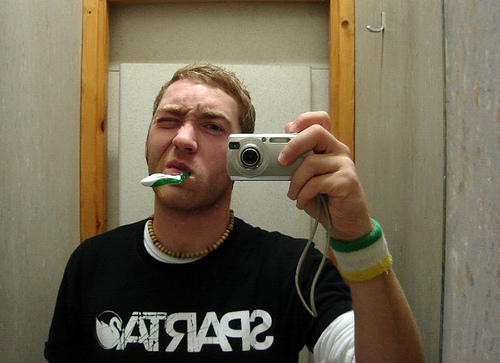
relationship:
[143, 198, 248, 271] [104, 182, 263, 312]
necklace around neck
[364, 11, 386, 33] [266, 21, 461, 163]
handle on wall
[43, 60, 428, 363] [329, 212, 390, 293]
man has wrist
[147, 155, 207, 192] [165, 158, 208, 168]
toothbrush in mouth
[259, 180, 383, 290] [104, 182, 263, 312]
man has neck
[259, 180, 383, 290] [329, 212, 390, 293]
man has wrist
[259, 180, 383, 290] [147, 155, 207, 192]
man has toothbrush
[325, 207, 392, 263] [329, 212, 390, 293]
wristband on wrist